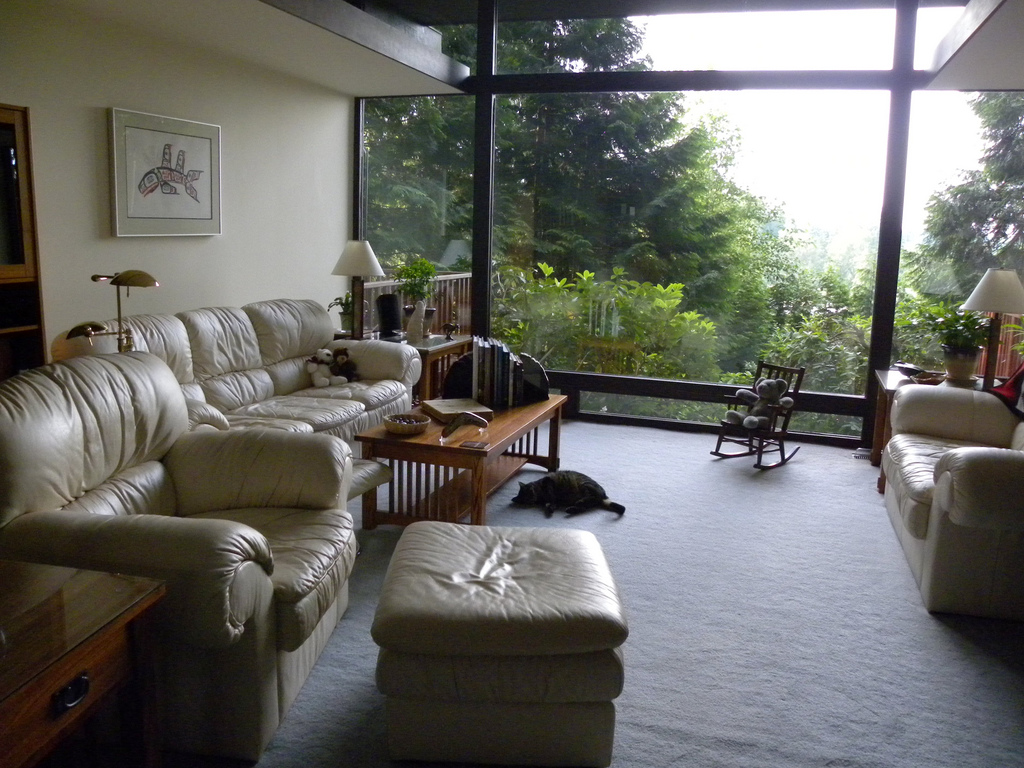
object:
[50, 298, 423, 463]
sofa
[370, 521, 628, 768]
ottoman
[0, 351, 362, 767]
armchair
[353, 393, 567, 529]
coffee table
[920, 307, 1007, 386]
houseplant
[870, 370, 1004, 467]
table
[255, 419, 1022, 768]
floor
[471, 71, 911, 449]
window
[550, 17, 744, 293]
tree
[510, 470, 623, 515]
cat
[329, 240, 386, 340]
lamp shade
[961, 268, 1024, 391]
lamp shade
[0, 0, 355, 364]
wall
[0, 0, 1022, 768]
house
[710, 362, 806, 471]
chair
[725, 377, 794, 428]
bear